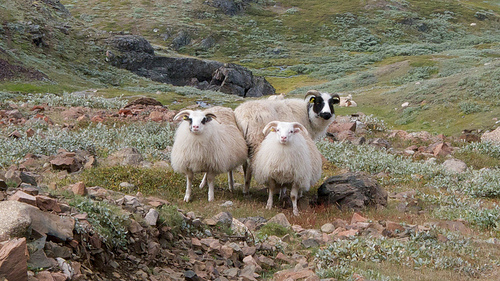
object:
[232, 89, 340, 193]
goat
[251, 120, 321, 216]
goat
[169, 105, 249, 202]
goat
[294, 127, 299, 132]
ear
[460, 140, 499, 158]
bushes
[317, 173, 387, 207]
rock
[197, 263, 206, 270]
rock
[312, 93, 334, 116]
face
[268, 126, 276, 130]
sheep ear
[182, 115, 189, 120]
sheep ear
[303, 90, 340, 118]
head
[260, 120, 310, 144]
head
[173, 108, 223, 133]
head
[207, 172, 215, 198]
sheep legs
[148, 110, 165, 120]
rock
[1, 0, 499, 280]
ground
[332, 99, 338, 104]
ear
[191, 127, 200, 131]
mouth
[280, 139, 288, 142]
mouth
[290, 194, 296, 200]
spot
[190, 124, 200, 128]
nose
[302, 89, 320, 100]
horn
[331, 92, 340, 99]
horn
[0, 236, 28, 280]
rock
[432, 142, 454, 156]
rock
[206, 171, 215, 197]
legs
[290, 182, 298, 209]
sheep's leg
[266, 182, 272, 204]
sheep's leg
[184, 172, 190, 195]
sheep's leg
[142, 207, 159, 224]
rock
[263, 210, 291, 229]
rock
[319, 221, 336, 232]
rock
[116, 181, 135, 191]
rock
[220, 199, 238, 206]
rock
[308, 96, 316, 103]
ear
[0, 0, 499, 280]
hill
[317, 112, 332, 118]
black nose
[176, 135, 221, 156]
wool